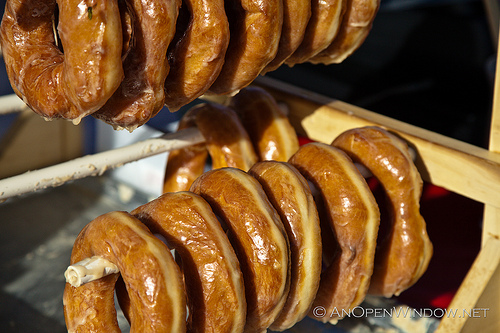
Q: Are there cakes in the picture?
A: Yes, there is a cake.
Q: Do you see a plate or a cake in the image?
A: Yes, there is a cake.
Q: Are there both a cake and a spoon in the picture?
A: No, there is a cake but no spoons.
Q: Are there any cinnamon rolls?
A: No, there are no cinnamon rolls.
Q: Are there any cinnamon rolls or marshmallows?
A: No, there are no cinnamon rolls or marshmallows.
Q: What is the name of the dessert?
A: The dessert is a cake.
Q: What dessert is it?
A: The dessert is a cake.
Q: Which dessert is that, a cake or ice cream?
A: This is a cake.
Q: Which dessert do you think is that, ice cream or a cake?
A: This is a cake.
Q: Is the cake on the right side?
A: Yes, the cake is on the right of the image.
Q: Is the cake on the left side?
A: No, the cake is on the right of the image.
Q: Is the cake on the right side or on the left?
A: The cake is on the right of the image.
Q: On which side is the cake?
A: The cake is on the right of the image.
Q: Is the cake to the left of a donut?
A: No, the cake is to the right of a donut.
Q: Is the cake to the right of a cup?
A: No, the cake is to the right of a donut.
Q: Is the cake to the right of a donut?
A: Yes, the cake is to the right of a donut.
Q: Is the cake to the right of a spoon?
A: No, the cake is to the right of a donut.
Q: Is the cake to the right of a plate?
A: No, the cake is to the right of a donut.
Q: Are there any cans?
A: No, there are no cans.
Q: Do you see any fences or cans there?
A: No, there are no cans or fences.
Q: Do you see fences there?
A: No, there are no fences.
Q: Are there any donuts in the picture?
A: Yes, there is a donut.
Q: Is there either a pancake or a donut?
A: Yes, there is a donut.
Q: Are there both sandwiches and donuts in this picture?
A: No, there is a donut but no sandwiches.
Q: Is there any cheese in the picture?
A: No, there is no cheese.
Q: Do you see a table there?
A: Yes, there is a table.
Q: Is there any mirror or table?
A: Yes, there is a table.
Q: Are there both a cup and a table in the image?
A: No, there is a table but no cups.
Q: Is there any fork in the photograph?
A: No, there are no forks.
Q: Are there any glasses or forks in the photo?
A: No, there are no forks or glasses.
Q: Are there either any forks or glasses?
A: No, there are no forks or glasses.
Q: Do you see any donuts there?
A: Yes, there is a donut.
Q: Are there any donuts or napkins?
A: Yes, there is a donut.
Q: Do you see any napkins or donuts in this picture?
A: Yes, there is a donut.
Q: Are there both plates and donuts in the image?
A: No, there is a donut but no plates.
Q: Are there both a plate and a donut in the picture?
A: No, there is a donut but no plates.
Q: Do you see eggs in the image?
A: No, there are no eggs.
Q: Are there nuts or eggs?
A: No, there are no eggs or nuts.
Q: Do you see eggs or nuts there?
A: No, there are no eggs or nuts.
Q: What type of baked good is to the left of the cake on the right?
A: The food is a donut.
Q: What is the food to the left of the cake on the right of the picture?
A: The food is a donut.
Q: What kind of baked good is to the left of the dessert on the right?
A: The food is a donut.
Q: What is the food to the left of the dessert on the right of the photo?
A: The food is a donut.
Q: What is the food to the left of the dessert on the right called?
A: The food is a donut.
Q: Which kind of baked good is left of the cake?
A: The food is a donut.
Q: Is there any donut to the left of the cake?
A: Yes, there is a donut to the left of the cake.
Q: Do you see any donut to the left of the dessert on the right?
A: Yes, there is a donut to the left of the cake.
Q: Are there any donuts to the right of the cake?
A: No, the donut is to the left of the cake.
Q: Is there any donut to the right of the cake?
A: No, the donut is to the left of the cake.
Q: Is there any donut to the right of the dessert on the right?
A: No, the donut is to the left of the cake.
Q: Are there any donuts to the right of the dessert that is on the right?
A: No, the donut is to the left of the cake.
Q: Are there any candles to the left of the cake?
A: No, there is a donut to the left of the cake.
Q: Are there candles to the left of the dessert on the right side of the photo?
A: No, there is a donut to the left of the cake.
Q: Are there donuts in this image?
A: Yes, there is a donut.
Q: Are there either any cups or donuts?
A: Yes, there is a donut.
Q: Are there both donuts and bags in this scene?
A: No, there is a donut but no bags.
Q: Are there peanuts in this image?
A: No, there are no peanuts.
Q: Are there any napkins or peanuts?
A: No, there are no peanuts or napkins.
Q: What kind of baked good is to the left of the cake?
A: The food is a donut.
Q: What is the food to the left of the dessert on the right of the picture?
A: The food is a donut.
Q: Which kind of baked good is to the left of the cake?
A: The food is a donut.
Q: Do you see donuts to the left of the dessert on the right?
A: Yes, there is a donut to the left of the cake.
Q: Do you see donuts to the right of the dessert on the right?
A: No, the donut is to the left of the cake.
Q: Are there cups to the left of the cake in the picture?
A: No, there is a donut to the left of the cake.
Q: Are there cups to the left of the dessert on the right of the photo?
A: No, there is a donut to the left of the cake.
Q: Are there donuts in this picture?
A: Yes, there is a donut.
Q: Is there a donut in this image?
A: Yes, there is a donut.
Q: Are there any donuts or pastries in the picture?
A: Yes, there is a donut.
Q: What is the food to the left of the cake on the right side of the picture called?
A: The food is a donut.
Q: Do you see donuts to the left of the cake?
A: Yes, there is a donut to the left of the cake.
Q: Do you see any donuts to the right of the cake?
A: No, the donut is to the left of the cake.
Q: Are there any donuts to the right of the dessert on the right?
A: No, the donut is to the left of the cake.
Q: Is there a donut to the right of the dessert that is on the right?
A: No, the donut is to the left of the cake.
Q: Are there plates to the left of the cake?
A: No, there is a donut to the left of the cake.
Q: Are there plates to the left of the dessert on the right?
A: No, there is a donut to the left of the cake.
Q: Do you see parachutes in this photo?
A: No, there are no parachutes.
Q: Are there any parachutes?
A: No, there are no parachutes.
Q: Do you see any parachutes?
A: No, there are no parachutes.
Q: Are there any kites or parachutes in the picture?
A: No, there are no parachutes or kites.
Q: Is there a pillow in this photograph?
A: No, there are no pillows.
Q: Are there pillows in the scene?
A: No, there are no pillows.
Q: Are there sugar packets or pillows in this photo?
A: No, there are no pillows or sugar packets.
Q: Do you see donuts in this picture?
A: Yes, there is a donut.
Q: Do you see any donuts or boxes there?
A: Yes, there is a donut.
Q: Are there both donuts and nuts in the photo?
A: No, there is a donut but no nuts.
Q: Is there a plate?
A: No, there are no plates.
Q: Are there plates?
A: No, there are no plates.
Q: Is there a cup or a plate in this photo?
A: No, there are no plates or cups.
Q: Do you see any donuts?
A: Yes, there is a donut.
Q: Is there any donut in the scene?
A: Yes, there is a donut.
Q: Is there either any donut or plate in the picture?
A: Yes, there is a donut.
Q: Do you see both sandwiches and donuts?
A: No, there is a donut but no sandwiches.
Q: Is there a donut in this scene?
A: Yes, there is a donut.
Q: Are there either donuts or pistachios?
A: Yes, there is a donut.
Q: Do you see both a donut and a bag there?
A: No, there is a donut but no bags.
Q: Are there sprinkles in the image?
A: No, there are no sprinkles.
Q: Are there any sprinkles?
A: No, there are no sprinkles.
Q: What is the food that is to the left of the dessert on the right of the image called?
A: The food is a donut.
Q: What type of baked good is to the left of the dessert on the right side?
A: The food is a donut.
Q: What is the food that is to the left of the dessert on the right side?
A: The food is a donut.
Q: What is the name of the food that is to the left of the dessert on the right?
A: The food is a donut.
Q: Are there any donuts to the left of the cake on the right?
A: Yes, there is a donut to the left of the cake.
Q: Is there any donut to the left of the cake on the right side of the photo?
A: Yes, there is a donut to the left of the cake.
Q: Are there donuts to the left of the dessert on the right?
A: Yes, there is a donut to the left of the cake.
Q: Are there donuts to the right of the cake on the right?
A: No, the donut is to the left of the cake.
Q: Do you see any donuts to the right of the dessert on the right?
A: No, the donut is to the left of the cake.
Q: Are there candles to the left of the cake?
A: No, there is a donut to the left of the cake.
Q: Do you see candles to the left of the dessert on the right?
A: No, there is a donut to the left of the cake.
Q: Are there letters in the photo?
A: Yes, there are letters.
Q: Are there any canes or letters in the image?
A: Yes, there are letters.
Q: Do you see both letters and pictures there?
A: No, there are letters but no pictures.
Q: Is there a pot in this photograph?
A: No, there are no pots.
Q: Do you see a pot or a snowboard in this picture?
A: No, there are no pots or snowboards.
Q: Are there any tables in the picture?
A: Yes, there is a table.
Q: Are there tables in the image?
A: Yes, there is a table.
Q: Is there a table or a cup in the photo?
A: Yes, there is a table.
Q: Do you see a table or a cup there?
A: Yes, there is a table.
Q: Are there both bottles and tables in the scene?
A: No, there is a table but no bottles.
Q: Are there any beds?
A: No, there are no beds.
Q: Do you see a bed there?
A: No, there are no beds.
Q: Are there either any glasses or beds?
A: No, there are no beds or glasses.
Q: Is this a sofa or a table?
A: This is a table.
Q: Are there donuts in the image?
A: Yes, there is a donut.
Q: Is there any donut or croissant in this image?
A: Yes, there is a donut.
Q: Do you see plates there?
A: No, there are no plates.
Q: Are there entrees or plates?
A: No, there are no plates or entrees.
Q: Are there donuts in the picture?
A: Yes, there is a donut.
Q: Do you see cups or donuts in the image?
A: Yes, there is a donut.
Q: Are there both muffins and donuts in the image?
A: No, there is a donut but no muffins.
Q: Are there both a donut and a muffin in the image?
A: No, there is a donut but no muffins.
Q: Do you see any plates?
A: No, there are no plates.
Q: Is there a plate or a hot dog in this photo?
A: No, there are no plates or hot dogs.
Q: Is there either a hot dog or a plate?
A: No, there are no plates or hot dogs.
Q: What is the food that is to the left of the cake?
A: The food is a donut.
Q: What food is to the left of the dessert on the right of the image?
A: The food is a donut.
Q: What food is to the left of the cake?
A: The food is a donut.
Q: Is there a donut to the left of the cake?
A: Yes, there is a donut to the left of the cake.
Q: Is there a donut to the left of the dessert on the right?
A: Yes, there is a donut to the left of the cake.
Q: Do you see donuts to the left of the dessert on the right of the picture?
A: Yes, there is a donut to the left of the cake.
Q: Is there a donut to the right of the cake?
A: No, the donut is to the left of the cake.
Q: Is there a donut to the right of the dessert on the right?
A: No, the donut is to the left of the cake.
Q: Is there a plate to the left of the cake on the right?
A: No, there is a donut to the left of the cake.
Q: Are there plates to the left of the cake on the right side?
A: No, there is a donut to the left of the cake.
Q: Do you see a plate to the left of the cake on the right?
A: No, there is a donut to the left of the cake.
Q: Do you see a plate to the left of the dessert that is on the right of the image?
A: No, there is a donut to the left of the cake.